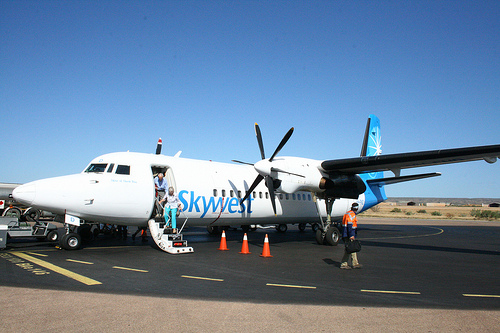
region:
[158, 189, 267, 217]
Blue Skywest name on airplane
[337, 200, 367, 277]
Person in orange top waling away from airplane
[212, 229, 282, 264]
Three orange cones with white tips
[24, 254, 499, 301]
Yellow stripes in front of ariplane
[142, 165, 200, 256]
Ladders for easy plane access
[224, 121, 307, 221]
Idle airplane engine with black rotors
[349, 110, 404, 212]
Blue airplane back wing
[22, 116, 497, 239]
White Skywest private airplane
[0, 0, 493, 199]
Clear blue skies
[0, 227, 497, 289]
Dark black asphalt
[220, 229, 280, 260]
three cones on the ground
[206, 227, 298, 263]
the cones are orange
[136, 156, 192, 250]
two people are unloading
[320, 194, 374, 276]
man is carrying a bag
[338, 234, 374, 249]
the bag is black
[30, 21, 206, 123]
the sky is blue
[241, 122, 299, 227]
the propeller is black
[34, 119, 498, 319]
the plane is small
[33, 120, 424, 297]
the plane is white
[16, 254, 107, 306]
the line is yellow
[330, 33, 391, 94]
part of the sky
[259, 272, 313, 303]
part of a white line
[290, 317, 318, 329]
part of a runway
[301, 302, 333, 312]
edge of a shadow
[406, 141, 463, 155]
edge of a wing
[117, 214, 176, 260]
edge of a staircase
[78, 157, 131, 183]
part of the front windows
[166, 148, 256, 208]
side of a plane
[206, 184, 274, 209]
section of some windows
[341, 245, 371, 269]
part of a bag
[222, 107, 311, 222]
the propeller of an aeroplane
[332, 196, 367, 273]
the man with the a bag in hand watching aeroplane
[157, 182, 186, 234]
an old women with green pant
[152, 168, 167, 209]
an old man with blue shirt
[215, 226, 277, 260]
the orange color bargates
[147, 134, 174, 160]
the red color signal indicator of an aeroplane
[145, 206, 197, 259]
the steps of an aeroplane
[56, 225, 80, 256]
the black color tyres of an aeroplane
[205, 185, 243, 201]
the windows of an aeroplane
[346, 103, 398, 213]
the blue color tail of an aeroplane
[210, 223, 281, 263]
three cones on the runway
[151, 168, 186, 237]
passengers walking out of the plane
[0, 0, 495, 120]
clear skies make for a beautiful day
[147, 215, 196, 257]
stairs/steps of the airplane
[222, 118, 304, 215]
propeller with six blades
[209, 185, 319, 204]
windows of the airplane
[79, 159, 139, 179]
cockpit where pilots control plane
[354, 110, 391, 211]
tail of the airplane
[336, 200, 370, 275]
man in a blue and orange jacket on the runway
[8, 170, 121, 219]
nose of the airplane